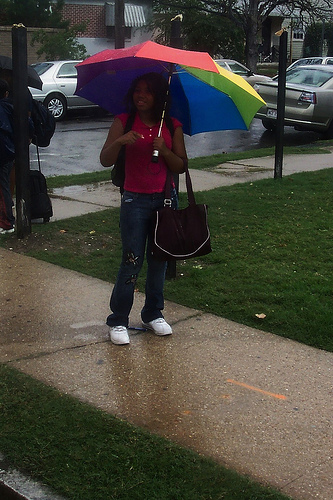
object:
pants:
[105, 187, 180, 329]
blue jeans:
[105, 189, 178, 328]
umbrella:
[72, 38, 267, 137]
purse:
[145, 157, 213, 262]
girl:
[100, 73, 189, 346]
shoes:
[109, 321, 130, 345]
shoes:
[139, 309, 172, 336]